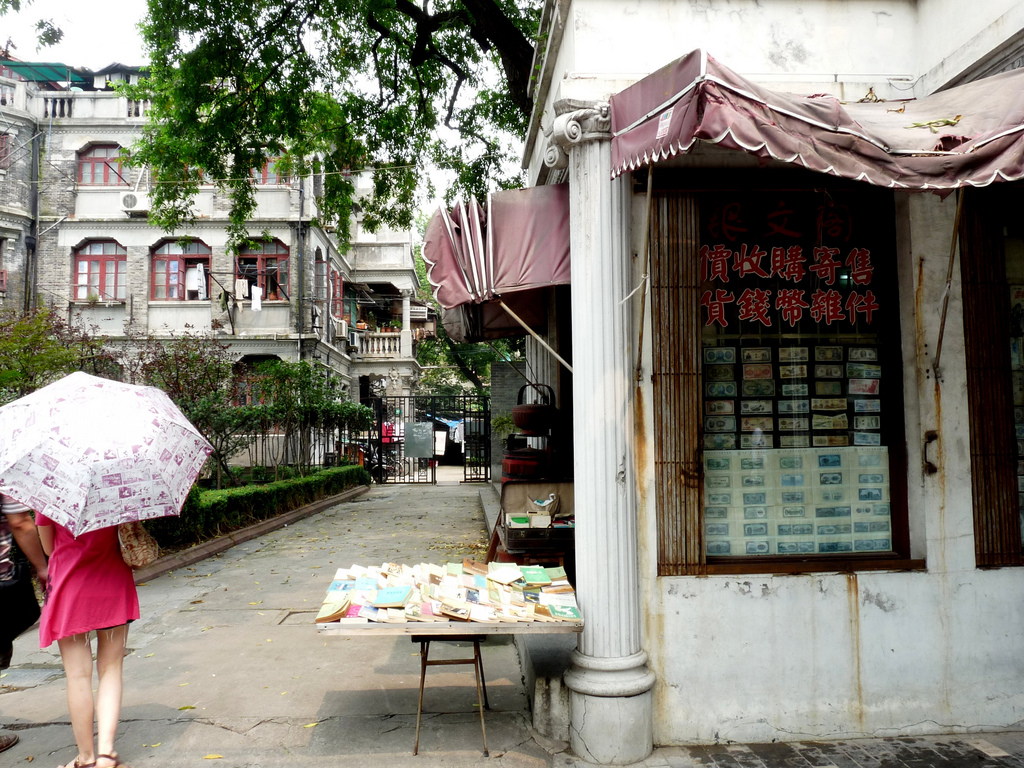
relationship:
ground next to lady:
[7, 463, 554, 764] [7, 370, 168, 764]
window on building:
[137, 225, 218, 318] [1, 50, 352, 465]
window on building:
[230, 124, 302, 189] [1, 50, 352, 465]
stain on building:
[910, 288, 952, 513] [486, 3, 992, 764]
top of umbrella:
[33, 378, 146, 497] [87, 470, 146, 617]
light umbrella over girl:
[17, 393, 184, 499] [13, 465, 175, 766]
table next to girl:
[310, 552, 592, 751] [13, 465, 175, 766]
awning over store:
[596, 57, 981, 200] [345, 18, 983, 744]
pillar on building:
[540, 122, 659, 749] [373, 24, 983, 744]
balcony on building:
[322, 243, 409, 360] [0, 33, 420, 414]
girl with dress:
[13, 465, 175, 766] [4, 482, 162, 649]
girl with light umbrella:
[13, 465, 175, 766] [0, 362, 237, 545]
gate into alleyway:
[374, 387, 504, 487] [387, 450, 509, 489]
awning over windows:
[595, 39, 1022, 200] [650, 147, 1022, 580]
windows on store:
[650, 147, 1022, 580] [417, 1, 1022, 764]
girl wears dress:
[13, 465, 175, 766] [9, 489, 163, 654]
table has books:
[311, 552, 599, 756] [309, 556, 590, 643]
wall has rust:
[616, 135, 1021, 754] [814, 564, 903, 731]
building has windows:
[0, 42, 424, 481] [52, 223, 297, 319]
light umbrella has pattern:
[0, 362, 237, 545] [97, 463, 136, 500]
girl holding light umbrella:
[17, 471, 175, 765] [0, 362, 237, 545]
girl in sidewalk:
[17, 471, 175, 765] [239, 503, 306, 750]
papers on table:
[309, 562, 575, 642] [311, 552, 599, 756]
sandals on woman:
[56, 748, 128, 764] [6, 476, 164, 764]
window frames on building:
[69, 245, 136, 310] [0, 42, 424, 481]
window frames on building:
[62, 135, 138, 203] [0, 42, 424, 481]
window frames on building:
[229, 249, 299, 304] [0, 42, 424, 481]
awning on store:
[595, 39, 1022, 200] [419, 0, 1024, 768]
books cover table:
[309, 556, 590, 643] [311, 552, 599, 756]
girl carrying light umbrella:
[13, 465, 175, 766] [0, 362, 237, 545]